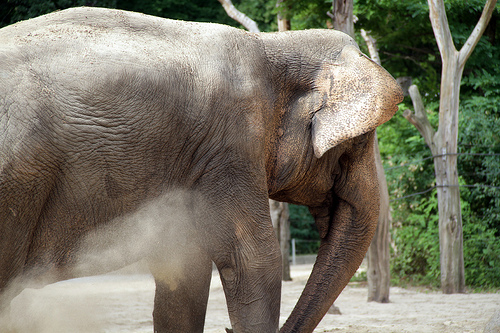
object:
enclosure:
[3, 1, 498, 329]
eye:
[359, 134, 369, 142]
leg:
[363, 237, 392, 301]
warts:
[276, 101, 287, 137]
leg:
[195, 193, 285, 333]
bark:
[217, 0, 261, 34]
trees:
[218, 0, 295, 283]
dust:
[0, 187, 218, 333]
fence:
[282, 238, 321, 264]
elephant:
[0, 5, 403, 332]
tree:
[402, 0, 496, 293]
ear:
[299, 43, 403, 160]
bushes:
[396, 73, 498, 290]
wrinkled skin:
[1, 29, 190, 195]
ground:
[19, 249, 497, 331]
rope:
[390, 184, 500, 203]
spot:
[99, 148, 155, 198]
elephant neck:
[256, 29, 308, 206]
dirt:
[20, 257, 499, 333]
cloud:
[72, 187, 226, 291]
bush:
[460, 101, 498, 291]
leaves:
[159, 0, 499, 293]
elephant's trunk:
[274, 156, 378, 332]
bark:
[408, 0, 498, 294]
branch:
[401, 84, 434, 150]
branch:
[457, 0, 498, 60]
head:
[275, 27, 403, 333]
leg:
[148, 238, 215, 333]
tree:
[327, 0, 392, 302]